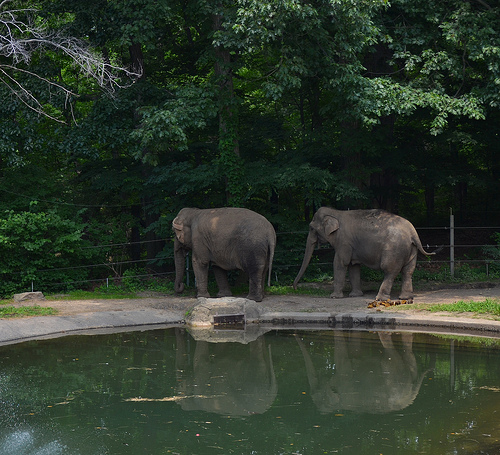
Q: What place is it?
A: It is a zoo.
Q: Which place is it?
A: It is a zoo.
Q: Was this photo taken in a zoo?
A: Yes, it was taken in a zoo.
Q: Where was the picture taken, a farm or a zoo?
A: It was taken at a zoo.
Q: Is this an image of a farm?
A: No, the picture is showing a zoo.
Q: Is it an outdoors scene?
A: Yes, it is outdoors.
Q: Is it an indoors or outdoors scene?
A: It is outdoors.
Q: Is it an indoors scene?
A: No, it is outdoors.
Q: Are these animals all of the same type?
A: Yes, all the animals are elephants.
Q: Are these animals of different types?
A: No, all the animals are elephants.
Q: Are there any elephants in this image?
A: Yes, there is an elephant.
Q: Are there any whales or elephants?
A: Yes, there is an elephant.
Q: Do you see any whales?
A: No, there are no whales.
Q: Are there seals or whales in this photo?
A: No, there are no whales or seals.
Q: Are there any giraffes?
A: No, there are no giraffes.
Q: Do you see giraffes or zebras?
A: No, there are no giraffes or zebras.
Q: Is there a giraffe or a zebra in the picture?
A: No, there are no giraffes or zebras.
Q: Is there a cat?
A: No, there are no cats.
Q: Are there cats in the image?
A: No, there are no cats.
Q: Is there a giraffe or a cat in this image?
A: No, there are no cats or giraffes.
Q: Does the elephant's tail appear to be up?
A: Yes, the tail is up.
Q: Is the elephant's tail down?
A: No, the tail is up.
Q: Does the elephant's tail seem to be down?
A: No, the tail is up.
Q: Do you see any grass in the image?
A: Yes, there is grass.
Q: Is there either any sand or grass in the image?
A: Yes, there is grass.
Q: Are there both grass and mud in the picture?
A: No, there is grass but no mud.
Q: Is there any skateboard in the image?
A: No, there are no skateboards.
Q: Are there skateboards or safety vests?
A: No, there are no skateboards or safety vests.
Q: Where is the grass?
A: The grass is on the ground.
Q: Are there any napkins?
A: No, there are no napkins.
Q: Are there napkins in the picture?
A: No, there are no napkins.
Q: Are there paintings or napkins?
A: No, there are no napkins or paintings.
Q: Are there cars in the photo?
A: No, there are no cars.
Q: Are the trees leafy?
A: Yes, the trees are leafy.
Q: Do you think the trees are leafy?
A: Yes, the trees are leafy.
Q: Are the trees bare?
A: No, the trees are leafy.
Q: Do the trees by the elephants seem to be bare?
A: No, the trees are leafy.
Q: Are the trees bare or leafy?
A: The trees are leafy.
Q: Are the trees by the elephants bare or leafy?
A: The trees are leafy.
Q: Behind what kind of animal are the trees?
A: The trees are behind the elephants.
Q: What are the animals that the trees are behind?
A: The animals are elephants.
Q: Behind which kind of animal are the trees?
A: The trees are behind the elephants.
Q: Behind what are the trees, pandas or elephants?
A: The trees are behind elephants.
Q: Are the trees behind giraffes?
A: No, the trees are behind the elephants.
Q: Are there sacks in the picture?
A: No, there are no sacks.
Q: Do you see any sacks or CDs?
A: No, there are no sacks or cds.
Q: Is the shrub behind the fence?
A: Yes, the shrub is behind the fence.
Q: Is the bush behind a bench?
A: No, the bush is behind the fence.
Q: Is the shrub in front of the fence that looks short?
A: No, the shrub is behind the fence.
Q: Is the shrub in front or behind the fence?
A: The shrub is behind the fence.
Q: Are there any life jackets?
A: No, there are no life jackets.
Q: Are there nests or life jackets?
A: No, there are no life jackets or nests.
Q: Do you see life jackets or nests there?
A: No, there are no life jackets or nests.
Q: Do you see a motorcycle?
A: No, there are no motorcycles.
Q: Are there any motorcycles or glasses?
A: No, there are no motorcycles or glasses.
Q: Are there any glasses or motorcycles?
A: No, there are no motorcycles or glasses.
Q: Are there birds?
A: No, there are no birds.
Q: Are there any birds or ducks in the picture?
A: No, there are no birds or ducks.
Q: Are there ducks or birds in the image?
A: No, there are no birds or ducks.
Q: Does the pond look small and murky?
A: Yes, the pond is small and murky.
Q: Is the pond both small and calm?
A: Yes, the pond is small and calm.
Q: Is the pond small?
A: Yes, the pond is small.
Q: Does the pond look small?
A: Yes, the pond is small.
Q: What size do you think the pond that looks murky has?
A: The pond has small size.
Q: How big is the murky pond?
A: The pond is small.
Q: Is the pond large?
A: No, the pond is small.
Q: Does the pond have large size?
A: No, the pond is small.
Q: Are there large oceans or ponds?
A: No, there is a pond but it is small.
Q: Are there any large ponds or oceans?
A: No, there is a pond but it is small.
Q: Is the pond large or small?
A: The pond is small.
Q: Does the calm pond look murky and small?
A: Yes, the pond is murky and small.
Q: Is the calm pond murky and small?
A: Yes, the pond is murky and small.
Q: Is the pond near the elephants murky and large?
A: No, the pond is murky but small.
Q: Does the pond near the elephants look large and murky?
A: No, the pond is murky but small.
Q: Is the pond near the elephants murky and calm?
A: Yes, the pond is murky and calm.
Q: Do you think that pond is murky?
A: Yes, the pond is murky.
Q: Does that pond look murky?
A: Yes, the pond is murky.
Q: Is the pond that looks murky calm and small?
A: Yes, the pond is calm and small.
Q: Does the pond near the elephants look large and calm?
A: No, the pond is calm but small.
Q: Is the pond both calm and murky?
A: Yes, the pond is calm and murky.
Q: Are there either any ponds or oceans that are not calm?
A: No, there is a pond but it is calm.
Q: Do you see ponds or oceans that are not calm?
A: No, there is a pond but it is calm.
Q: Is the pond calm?
A: Yes, the pond is calm.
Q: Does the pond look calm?
A: Yes, the pond is calm.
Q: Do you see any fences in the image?
A: Yes, there is a fence.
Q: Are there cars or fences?
A: Yes, there is a fence.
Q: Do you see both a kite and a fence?
A: No, there is a fence but no kites.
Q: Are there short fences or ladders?
A: Yes, there is a short fence.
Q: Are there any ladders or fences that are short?
A: Yes, the fence is short.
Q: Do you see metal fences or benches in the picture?
A: Yes, there is a metal fence.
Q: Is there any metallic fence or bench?
A: Yes, there is a metal fence.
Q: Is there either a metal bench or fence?
A: Yes, there is a metal fence.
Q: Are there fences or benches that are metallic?
A: Yes, the fence is metallic.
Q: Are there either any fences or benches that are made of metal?
A: Yes, the fence is made of metal.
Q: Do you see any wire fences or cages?
A: Yes, there is a wire fence.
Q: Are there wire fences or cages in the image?
A: Yes, there is a wire fence.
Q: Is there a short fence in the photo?
A: Yes, there is a short fence.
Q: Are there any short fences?
A: Yes, there is a short fence.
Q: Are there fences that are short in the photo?
A: Yes, there is a short fence.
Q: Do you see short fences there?
A: Yes, there is a short fence.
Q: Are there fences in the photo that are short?
A: Yes, there is a fence that is short.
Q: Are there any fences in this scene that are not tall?
A: Yes, there is a short fence.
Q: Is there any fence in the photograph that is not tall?
A: Yes, there is a short fence.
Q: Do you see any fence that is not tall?
A: Yes, there is a short fence.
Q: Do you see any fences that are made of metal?
A: Yes, there is a fence that is made of metal.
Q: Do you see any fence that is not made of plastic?
A: Yes, there is a fence that is made of metal.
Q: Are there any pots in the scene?
A: No, there are no pots.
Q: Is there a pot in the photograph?
A: No, there are no pots.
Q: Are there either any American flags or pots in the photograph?
A: No, there are no pots or American flags.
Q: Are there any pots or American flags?
A: No, there are no pots or American flags.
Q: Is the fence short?
A: Yes, the fence is short.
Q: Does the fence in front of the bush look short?
A: Yes, the fence is short.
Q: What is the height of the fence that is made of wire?
A: The fence is short.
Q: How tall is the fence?
A: The fence is short.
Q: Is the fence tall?
A: No, the fence is short.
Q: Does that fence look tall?
A: No, the fence is short.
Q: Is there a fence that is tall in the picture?
A: No, there is a fence but it is short.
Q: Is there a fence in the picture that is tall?
A: No, there is a fence but it is short.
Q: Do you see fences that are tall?
A: No, there is a fence but it is short.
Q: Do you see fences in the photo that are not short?
A: No, there is a fence but it is short.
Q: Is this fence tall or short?
A: The fence is short.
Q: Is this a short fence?
A: Yes, this is a short fence.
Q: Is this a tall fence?
A: No, this is a short fence.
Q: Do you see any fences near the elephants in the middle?
A: Yes, there is a fence near the elephants.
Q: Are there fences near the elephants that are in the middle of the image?
A: Yes, there is a fence near the elephants.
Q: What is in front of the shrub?
A: The fence is in front of the shrub.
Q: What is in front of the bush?
A: The fence is in front of the shrub.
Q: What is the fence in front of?
A: The fence is in front of the shrub.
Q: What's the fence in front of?
A: The fence is in front of the shrub.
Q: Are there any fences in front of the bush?
A: Yes, there is a fence in front of the bush.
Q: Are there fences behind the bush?
A: No, the fence is in front of the bush.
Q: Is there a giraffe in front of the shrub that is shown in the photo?
A: No, there is a fence in front of the shrub.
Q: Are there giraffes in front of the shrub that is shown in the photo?
A: No, there is a fence in front of the shrub.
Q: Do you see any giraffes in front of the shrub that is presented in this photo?
A: No, there is a fence in front of the shrub.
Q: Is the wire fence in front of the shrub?
A: Yes, the fence is in front of the shrub.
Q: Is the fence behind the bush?
A: No, the fence is in front of the bush.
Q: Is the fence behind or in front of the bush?
A: The fence is in front of the bush.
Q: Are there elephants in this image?
A: Yes, there are elephants.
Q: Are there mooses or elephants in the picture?
A: Yes, there are elephants.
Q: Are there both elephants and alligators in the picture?
A: No, there are elephants but no alligators.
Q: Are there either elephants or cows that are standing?
A: Yes, the elephants are standing.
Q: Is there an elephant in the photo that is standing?
A: Yes, there are elephants that are standing.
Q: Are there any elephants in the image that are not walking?
A: Yes, there are elephants that are standing.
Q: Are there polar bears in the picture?
A: No, there are no polar bears.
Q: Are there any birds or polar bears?
A: No, there are no polar bears or birds.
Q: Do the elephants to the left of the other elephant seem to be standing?
A: Yes, the elephants are standing.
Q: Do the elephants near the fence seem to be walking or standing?
A: The elephants are standing.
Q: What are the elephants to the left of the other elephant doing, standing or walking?
A: The elephants are standing.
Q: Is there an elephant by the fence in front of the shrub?
A: Yes, there are elephants by the fence.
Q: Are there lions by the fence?
A: No, there are elephants by the fence.